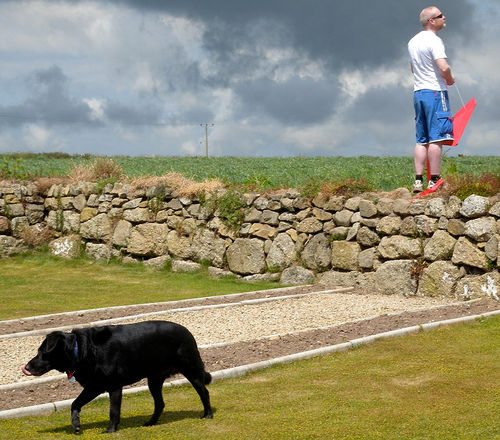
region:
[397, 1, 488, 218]
a man in blue shorts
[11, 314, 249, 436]
a full grown black lab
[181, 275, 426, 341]
a straight gravel walkway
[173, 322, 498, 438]
some short cut grass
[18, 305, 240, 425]
a dog wearing a bandana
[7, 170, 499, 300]
a long rock wall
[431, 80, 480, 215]
a bright red kite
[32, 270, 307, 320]
a row of dirt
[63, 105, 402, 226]
a large over grown field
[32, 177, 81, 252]
small plants between stones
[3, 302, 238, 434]
the dog is black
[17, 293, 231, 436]
a dog in the picture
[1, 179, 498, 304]
a stuck of stones on the side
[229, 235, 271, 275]
this is a stone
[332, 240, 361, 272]
this is a stone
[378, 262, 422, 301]
this is a stone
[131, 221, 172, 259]
this is a stone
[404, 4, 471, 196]
this is a person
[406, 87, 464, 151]
the man is wearing blue shorts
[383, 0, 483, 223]
the man has a kite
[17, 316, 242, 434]
dog walking on grass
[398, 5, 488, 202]
man with a kite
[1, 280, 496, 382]
bordered walkway with stones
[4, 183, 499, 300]
stone wall with irregular stones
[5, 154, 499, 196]
green field in background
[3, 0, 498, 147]
gray and white overcast skies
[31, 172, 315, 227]
plant growth on the wall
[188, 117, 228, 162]
telephone pole in the distance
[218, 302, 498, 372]
raised border of walkway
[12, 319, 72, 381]
dog licking his nose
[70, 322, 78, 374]
the colar is blue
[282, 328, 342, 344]
the sand is brown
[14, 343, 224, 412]
the dog has tongue out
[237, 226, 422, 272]
the wall is made of stones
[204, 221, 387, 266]
the stones are piled up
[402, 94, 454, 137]
the shorts are blue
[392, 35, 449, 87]
the shirt is white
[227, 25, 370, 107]
the sky is cloudy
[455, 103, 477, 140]
the kite is red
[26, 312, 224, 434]
a black dog walking in the road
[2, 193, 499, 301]
a stone fence next to the yard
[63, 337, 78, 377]
the blue collar on the dog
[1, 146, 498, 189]
the green grass growing in the field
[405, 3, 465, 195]
a man standing on the fence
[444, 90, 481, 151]
the kite the man is holding onto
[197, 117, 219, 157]
a pole standing in the field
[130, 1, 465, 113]
the dark cloud in the sky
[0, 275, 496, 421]
a path for people to walk along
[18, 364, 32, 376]
the tongue of the dog sticking out